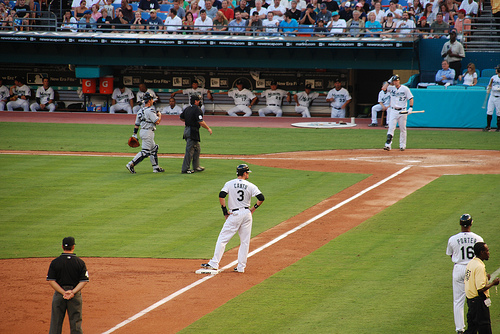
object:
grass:
[0, 122, 499, 334]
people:
[274, 11, 298, 37]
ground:
[0, 111, 500, 332]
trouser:
[206, 206, 253, 273]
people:
[192, 8, 210, 32]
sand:
[248, 148, 498, 176]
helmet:
[235, 164, 250, 175]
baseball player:
[124, 90, 164, 172]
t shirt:
[43, 251, 89, 291]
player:
[200, 163, 264, 275]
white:
[235, 212, 250, 228]